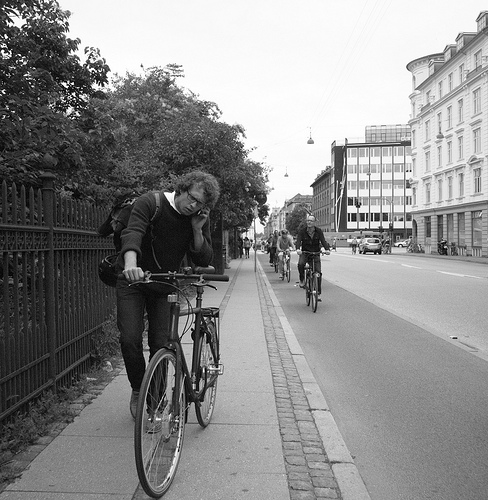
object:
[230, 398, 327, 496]
pavement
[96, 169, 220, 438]
man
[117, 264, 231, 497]
bicycle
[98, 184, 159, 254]
back pack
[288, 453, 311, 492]
brick area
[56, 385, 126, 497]
sidewalk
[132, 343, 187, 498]
wheel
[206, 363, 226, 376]
foot pedal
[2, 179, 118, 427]
gate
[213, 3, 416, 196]
wires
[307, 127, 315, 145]
object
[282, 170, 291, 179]
object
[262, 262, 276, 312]
line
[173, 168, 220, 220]
man/glasses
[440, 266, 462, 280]
line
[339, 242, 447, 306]
sidewalk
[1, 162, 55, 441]
metal fence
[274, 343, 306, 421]
bricks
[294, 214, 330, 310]
rider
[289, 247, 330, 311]
bike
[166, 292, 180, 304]
reflector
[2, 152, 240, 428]
fence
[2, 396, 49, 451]
weeds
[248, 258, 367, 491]
curb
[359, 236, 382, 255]
car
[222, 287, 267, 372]
sidewalk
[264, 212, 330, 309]
people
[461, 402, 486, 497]
street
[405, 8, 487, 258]
building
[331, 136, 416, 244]
building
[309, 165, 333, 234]
building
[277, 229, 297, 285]
bikers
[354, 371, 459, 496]
road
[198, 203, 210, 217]
phone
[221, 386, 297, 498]
sidewalk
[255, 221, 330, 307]
row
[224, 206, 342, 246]
distance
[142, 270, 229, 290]
bars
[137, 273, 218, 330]
front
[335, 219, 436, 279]
distance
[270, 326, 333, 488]
row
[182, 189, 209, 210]
glasses